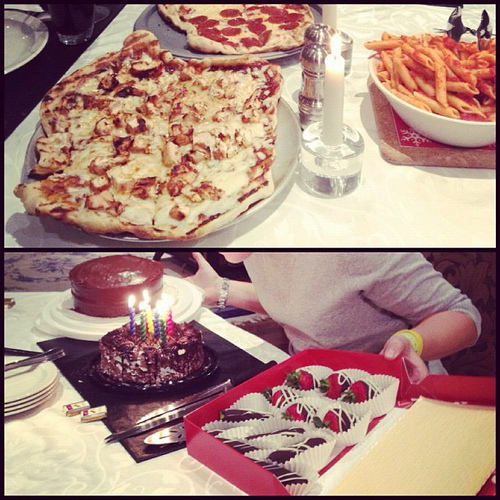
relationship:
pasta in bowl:
[362, 27, 497, 124] [361, 54, 498, 155]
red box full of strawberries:
[187, 348, 497, 499] [348, 380, 383, 405]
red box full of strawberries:
[187, 348, 497, 499] [321, 400, 351, 432]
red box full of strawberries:
[187, 348, 497, 499] [321, 362, 352, 393]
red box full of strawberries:
[187, 348, 497, 499] [289, 360, 313, 385]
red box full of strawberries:
[187, 348, 497, 499] [268, 383, 296, 405]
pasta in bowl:
[369, 20, 496, 121] [367, 56, 500, 146]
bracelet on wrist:
[216, 269, 235, 314] [210, 262, 239, 314]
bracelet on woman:
[216, 269, 235, 314] [181, 245, 484, 402]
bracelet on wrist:
[401, 333, 418, 349] [388, 323, 440, 351]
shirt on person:
[245, 255, 466, 372] [179, 252, 484, 376]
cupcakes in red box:
[202, 408, 334, 490] [187, 348, 497, 499]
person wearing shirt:
[179, 252, 481, 383] [242, 252, 482, 375]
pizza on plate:
[11, 25, 285, 242] [25, 95, 302, 239]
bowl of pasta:
[333, 43, 490, 168] [369, 32, 484, 134]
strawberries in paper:
[313, 408, 350, 432] [275, 437, 336, 462]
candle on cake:
[118, 296, 140, 341] [80, 302, 227, 384]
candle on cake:
[166, 306, 176, 335] [90, 305, 299, 407]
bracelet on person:
[217, 278, 229, 308] [179, 252, 481, 383]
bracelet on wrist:
[217, 278, 229, 308] [211, 268, 241, 315]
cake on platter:
[66, 253, 165, 318] [36, 275, 204, 340]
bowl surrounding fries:
[367, 56, 500, 146] [363, 32, 497, 121]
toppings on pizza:
[190, 4, 303, 42] [153, 2, 322, 65]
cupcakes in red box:
[268, 438, 328, 463] [187, 348, 497, 499]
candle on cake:
[129, 308, 135, 334] [100, 322, 203, 384]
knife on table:
[105, 357, 277, 442] [4, 248, 499, 498]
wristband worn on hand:
[400, 324, 428, 354] [377, 321, 431, 386]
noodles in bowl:
[365, 31, 495, 121] [368, 48, 496, 147]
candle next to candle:
[129, 308, 135, 334] [160, 290, 179, 342]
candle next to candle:
[133, 297, 148, 341] [140, 289, 159, 335]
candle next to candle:
[140, 289, 159, 335] [151, 297, 166, 333]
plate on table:
[4, 359, 57, 403] [4, 248, 499, 498]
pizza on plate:
[11, 25, 285, 242] [18, 53, 306, 250]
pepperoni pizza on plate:
[159, 3, 313, 54] [127, 4, 329, 72]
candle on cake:
[129, 308, 135, 334] [91, 328, 223, 385]